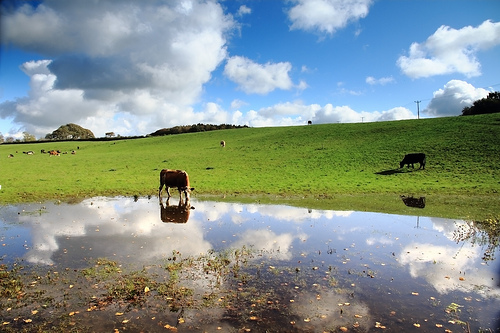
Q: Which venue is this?
A: This is a field.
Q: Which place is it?
A: It is a field.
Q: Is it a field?
A: Yes, it is a field.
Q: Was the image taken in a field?
A: Yes, it was taken in a field.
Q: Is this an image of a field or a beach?
A: It is showing a field.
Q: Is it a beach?
A: No, it is a field.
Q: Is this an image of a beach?
A: No, the picture is showing a field.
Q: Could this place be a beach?
A: No, it is a field.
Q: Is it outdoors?
A: Yes, it is outdoors.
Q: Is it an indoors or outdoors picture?
A: It is outdoors.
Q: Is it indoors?
A: No, it is outdoors.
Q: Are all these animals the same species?
A: Yes, all the animals are cows.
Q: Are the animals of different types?
A: No, all the animals are cows.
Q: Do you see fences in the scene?
A: No, there are no fences.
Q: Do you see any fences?
A: No, there are no fences.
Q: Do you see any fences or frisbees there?
A: No, there are no fences or frisbees.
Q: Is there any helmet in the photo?
A: No, there are no helmets.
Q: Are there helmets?
A: No, there are no helmets.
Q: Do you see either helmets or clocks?
A: No, there are no helmets or clocks.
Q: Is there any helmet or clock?
A: No, there are no helmets or clocks.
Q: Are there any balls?
A: No, there are no balls.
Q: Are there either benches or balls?
A: No, there are no balls or benches.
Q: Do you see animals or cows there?
A: Yes, there is a cow.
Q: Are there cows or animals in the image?
A: Yes, there is a cow.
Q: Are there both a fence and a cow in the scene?
A: No, there is a cow but no fences.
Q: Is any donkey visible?
A: No, there are no donkeys.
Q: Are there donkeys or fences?
A: No, there are no donkeys or fences.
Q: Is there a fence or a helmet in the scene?
A: No, there are no fences or helmets.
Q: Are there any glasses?
A: No, there are no glasses.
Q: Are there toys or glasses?
A: No, there are no glasses or toys.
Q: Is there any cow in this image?
A: Yes, there is a cow.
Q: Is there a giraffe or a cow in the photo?
A: Yes, there is a cow.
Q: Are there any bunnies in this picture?
A: No, there are no bunnies.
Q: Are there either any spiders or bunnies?
A: No, there are no bunnies or spiders.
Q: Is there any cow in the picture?
A: Yes, there is a cow.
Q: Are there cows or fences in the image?
A: Yes, there is a cow.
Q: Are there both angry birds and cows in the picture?
A: No, there is a cow but no angry birds.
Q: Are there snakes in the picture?
A: No, there are no snakes.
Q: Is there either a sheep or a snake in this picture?
A: No, there are no snakes or sheep.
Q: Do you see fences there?
A: No, there are no fences.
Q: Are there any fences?
A: No, there are no fences.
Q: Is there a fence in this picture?
A: No, there are no fences.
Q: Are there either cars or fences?
A: No, there are no fences or cars.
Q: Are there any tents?
A: No, there are no tents.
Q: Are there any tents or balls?
A: No, there are no tents or balls.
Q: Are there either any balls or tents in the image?
A: No, there are no tents or balls.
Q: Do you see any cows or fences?
A: Yes, there are cows.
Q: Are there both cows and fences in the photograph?
A: No, there are cows but no fences.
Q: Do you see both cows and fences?
A: No, there are cows but no fences.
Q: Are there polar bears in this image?
A: No, there are no polar bears.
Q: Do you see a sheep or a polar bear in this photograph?
A: No, there are no polar bears or sheep.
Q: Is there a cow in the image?
A: Yes, there are cows.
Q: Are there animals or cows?
A: Yes, there are cows.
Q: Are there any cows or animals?
A: Yes, there are cows.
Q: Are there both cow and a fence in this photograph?
A: No, there are cows but no fences.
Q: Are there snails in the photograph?
A: No, there are no snails.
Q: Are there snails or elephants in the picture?
A: No, there are no snails or elephants.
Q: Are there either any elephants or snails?
A: No, there are no snails or elephants.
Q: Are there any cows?
A: Yes, there are cows.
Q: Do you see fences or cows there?
A: Yes, there are cows.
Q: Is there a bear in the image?
A: No, there are no bears.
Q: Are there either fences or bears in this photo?
A: No, there are no bears or fences.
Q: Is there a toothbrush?
A: No, there are no toothbrushes.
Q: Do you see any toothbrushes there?
A: No, there are no toothbrushes.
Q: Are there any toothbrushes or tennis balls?
A: No, there are no toothbrushes or tennis balls.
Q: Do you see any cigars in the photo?
A: No, there are no cigars.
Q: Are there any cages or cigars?
A: No, there are no cigars or cages.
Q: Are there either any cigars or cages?
A: No, there are no cigars or cages.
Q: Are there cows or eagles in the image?
A: Yes, there is a cow.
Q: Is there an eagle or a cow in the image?
A: Yes, there is a cow.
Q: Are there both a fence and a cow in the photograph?
A: No, there is a cow but no fences.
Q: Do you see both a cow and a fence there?
A: No, there is a cow but no fences.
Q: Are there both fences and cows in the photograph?
A: No, there is a cow but no fences.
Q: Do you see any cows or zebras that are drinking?
A: Yes, the cow is drinking.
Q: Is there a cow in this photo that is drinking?
A: Yes, there is a cow that is drinking.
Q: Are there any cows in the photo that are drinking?
A: Yes, there is a cow that is drinking.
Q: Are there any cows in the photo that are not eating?
A: Yes, there is a cow that is drinking.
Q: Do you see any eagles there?
A: No, there are no eagles.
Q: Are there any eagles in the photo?
A: No, there are no eagles.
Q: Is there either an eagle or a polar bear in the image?
A: No, there are no eagles or polar bears.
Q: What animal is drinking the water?
A: The cow is drinking the water.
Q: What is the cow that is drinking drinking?
A: The cow is drinking water.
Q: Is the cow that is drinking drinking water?
A: Yes, the cow is drinking water.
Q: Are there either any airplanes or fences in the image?
A: No, there are no fences or airplanes.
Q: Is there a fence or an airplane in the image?
A: No, there are no fences or airplanes.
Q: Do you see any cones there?
A: No, there are no cones.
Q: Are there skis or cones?
A: No, there are no cones or skis.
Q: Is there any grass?
A: Yes, there is grass.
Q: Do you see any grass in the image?
A: Yes, there is grass.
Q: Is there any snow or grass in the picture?
A: Yes, there is grass.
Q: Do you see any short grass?
A: Yes, there is short grass.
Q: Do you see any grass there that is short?
A: Yes, there is grass that is short.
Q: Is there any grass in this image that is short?
A: Yes, there is grass that is short.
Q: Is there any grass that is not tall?
A: Yes, there is short grass.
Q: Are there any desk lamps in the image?
A: No, there are no desk lamps.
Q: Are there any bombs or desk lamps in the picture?
A: No, there are no desk lamps or bombs.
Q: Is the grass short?
A: Yes, the grass is short.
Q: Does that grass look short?
A: Yes, the grass is short.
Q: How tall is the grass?
A: The grass is short.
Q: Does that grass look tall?
A: No, the grass is short.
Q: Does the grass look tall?
A: No, the grass is short.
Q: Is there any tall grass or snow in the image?
A: No, there is grass but it is short.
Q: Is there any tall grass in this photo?
A: No, there is grass but it is short.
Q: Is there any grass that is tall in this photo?
A: No, there is grass but it is short.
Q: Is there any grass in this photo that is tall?
A: No, there is grass but it is short.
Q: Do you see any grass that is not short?
A: No, there is grass but it is short.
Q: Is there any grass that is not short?
A: No, there is grass but it is short.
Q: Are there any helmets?
A: No, there are no helmets.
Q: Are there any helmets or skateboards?
A: No, there are no helmets or skateboards.